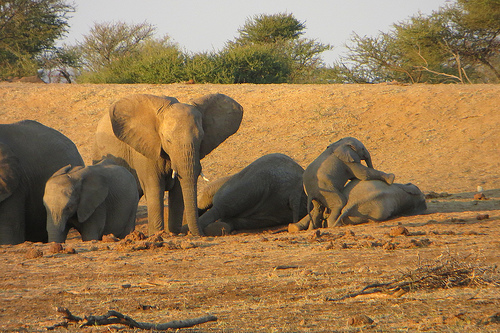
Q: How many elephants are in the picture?
A: Six.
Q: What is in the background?
A: Trees.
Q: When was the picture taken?
A: Daytime.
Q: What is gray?
A: Elephants.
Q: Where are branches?
A: On the ground.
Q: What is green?
A: Trees.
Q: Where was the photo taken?
A: In a field.